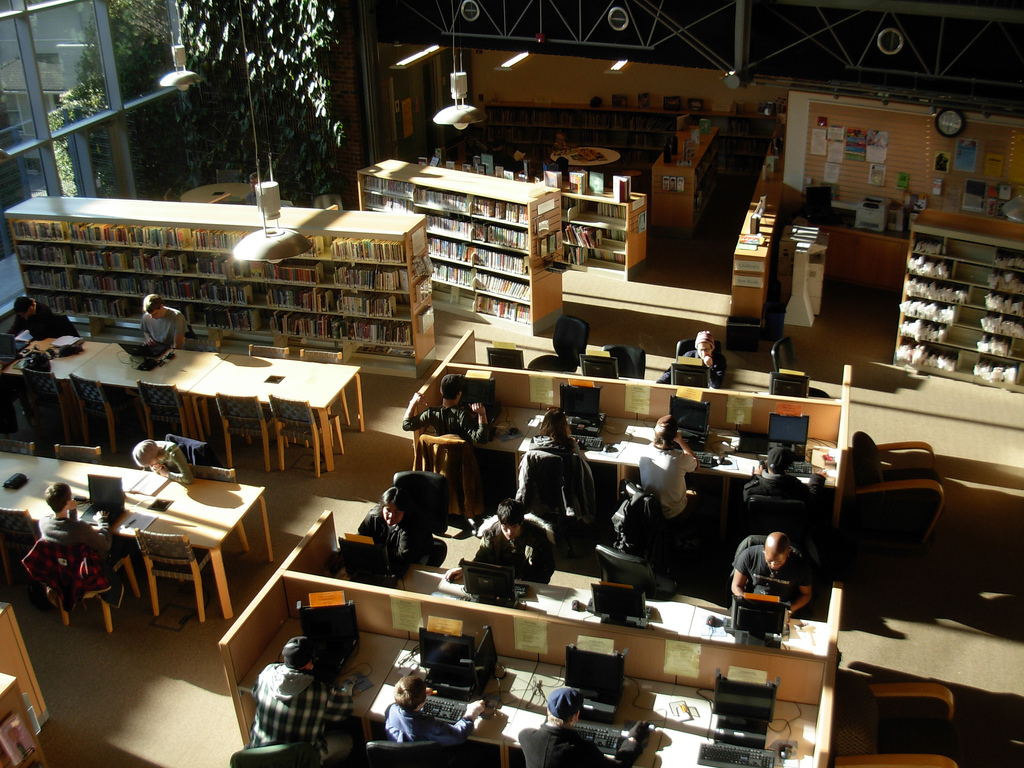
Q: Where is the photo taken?
A: In a house.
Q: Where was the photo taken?
A: In the library.